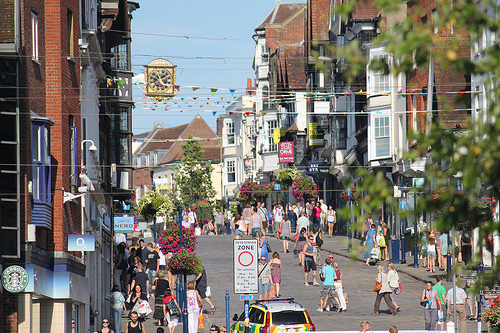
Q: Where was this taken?
A: Street.